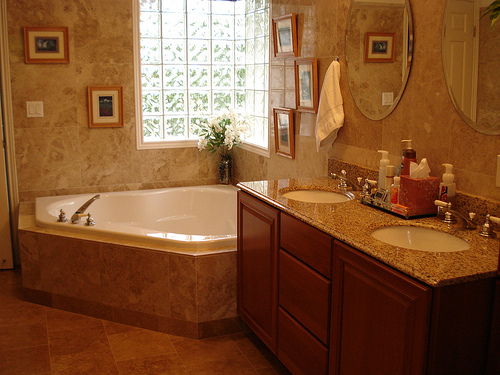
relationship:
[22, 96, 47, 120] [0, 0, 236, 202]
light switches on wall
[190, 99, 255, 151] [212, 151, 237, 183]
flowers in vase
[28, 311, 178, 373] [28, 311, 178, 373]
tiles on tiles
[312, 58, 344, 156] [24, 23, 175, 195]
towel hanging on wall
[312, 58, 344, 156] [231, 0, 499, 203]
towel hanging on wall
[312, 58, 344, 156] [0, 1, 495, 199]
towel hanging on wall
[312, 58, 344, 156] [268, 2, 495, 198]
towel hanging on wall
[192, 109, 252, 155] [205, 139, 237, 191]
flowers in vase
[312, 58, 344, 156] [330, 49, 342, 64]
towel hanging on hook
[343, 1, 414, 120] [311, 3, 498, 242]
mirrors hanging on wall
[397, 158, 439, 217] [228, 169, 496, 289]
box on counter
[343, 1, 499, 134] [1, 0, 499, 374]
mirrors on bathroom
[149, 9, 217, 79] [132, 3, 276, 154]
glass blocks on bathroom window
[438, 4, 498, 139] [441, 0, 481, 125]
reflection on door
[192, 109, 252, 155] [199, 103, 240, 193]
flowers in vase